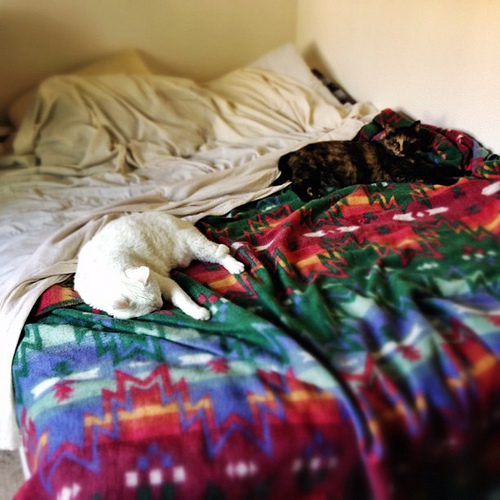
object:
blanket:
[7, 111, 500, 500]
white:
[2, 166, 67, 235]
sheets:
[0, 69, 386, 459]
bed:
[2, 44, 500, 499]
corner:
[276, 2, 315, 40]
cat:
[269, 120, 476, 209]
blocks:
[167, 465, 190, 486]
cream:
[436, 2, 499, 71]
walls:
[295, 1, 500, 113]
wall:
[0, 0, 304, 117]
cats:
[67, 194, 254, 326]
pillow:
[2, 43, 177, 153]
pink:
[355, 233, 380, 245]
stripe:
[97, 365, 192, 412]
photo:
[0, 0, 499, 498]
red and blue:
[98, 371, 197, 409]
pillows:
[190, 45, 349, 170]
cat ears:
[126, 263, 159, 290]